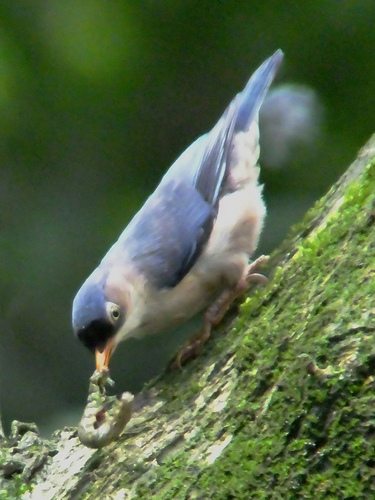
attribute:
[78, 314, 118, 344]
spot — black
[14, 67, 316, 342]
bird — blue, white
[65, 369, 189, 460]
worm — green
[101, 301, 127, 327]
eye — white, black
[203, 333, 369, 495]
moss — green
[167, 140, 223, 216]
feathers — Blue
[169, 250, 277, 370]
legs — red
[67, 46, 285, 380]
bird — dark, light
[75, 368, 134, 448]
worm — green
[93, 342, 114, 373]
beak — orange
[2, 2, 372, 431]
green background — fuzzy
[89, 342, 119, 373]
beak — Black  , bird's 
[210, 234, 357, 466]
trunk — tree